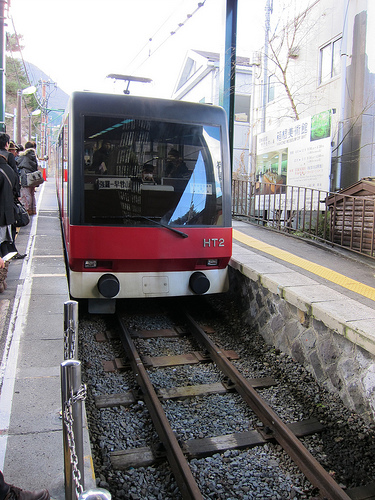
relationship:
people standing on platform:
[0, 132, 21, 244] [1, 178, 62, 496]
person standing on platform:
[8, 139, 16, 156] [1, 178, 62, 496]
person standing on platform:
[25, 138, 35, 151] [1, 178, 62, 496]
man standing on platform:
[0, 149, 16, 262] [1, 178, 62, 496]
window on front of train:
[75, 110, 232, 229] [49, 87, 236, 316]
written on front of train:
[195, 234, 229, 251] [51, 95, 256, 301]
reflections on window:
[95, 138, 215, 214] [82, 116, 226, 226]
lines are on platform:
[23, 195, 43, 426] [1, 176, 71, 496]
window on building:
[317, 32, 345, 86] [250, 0, 368, 225]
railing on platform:
[241, 172, 369, 250] [220, 205, 372, 450]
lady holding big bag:
[9, 138, 54, 231] [20, 170, 47, 190]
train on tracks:
[49, 87, 236, 316] [94, 311, 373, 499]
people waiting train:
[0, 128, 47, 273] [49, 87, 236, 316]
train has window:
[49, 87, 236, 316] [82, 116, 226, 226]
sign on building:
[233, 111, 373, 243] [232, 60, 373, 219]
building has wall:
[250, 0, 375, 261] [253, 0, 368, 219]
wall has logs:
[253, 0, 368, 219] [321, 173, 374, 261]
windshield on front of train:
[71, 114, 210, 231] [49, 87, 236, 316]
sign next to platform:
[252, 107, 337, 213] [220, 205, 372, 450]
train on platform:
[49, 87, 236, 316] [6, 179, 372, 498]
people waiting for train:
[0, 128, 47, 273] [49, 87, 236, 316]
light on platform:
[4, 69, 43, 150] [0, 137, 58, 343]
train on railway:
[49, 87, 236, 316] [79, 294, 375, 499]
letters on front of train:
[202, 236, 215, 246] [52, 72, 232, 298]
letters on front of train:
[275, 121, 308, 145] [52, 72, 232, 298]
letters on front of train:
[258, 135, 276, 147] [52, 72, 232, 298]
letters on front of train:
[289, 146, 324, 193] [52, 72, 232, 298]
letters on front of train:
[255, 194, 324, 209] [52, 72, 232, 298]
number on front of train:
[218, 235, 223, 247] [52, 72, 232, 298]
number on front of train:
[121, 178, 125, 189] [52, 72, 232, 298]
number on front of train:
[105, 179, 110, 189] [52, 72, 232, 298]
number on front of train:
[113, 179, 119, 188] [52, 72, 232, 298]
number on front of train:
[100, 181, 105, 189] [52, 72, 232, 298]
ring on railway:
[58, 356, 81, 369] [100, 305, 306, 410]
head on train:
[73, 91, 230, 116] [49, 87, 236, 316]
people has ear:
[0, 132, 21, 244] [5, 137, 11, 148]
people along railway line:
[0, 132, 21, 244] [60, 311, 251, 373]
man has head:
[0, 130, 28, 256] [1, 130, 13, 150]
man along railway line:
[0, 130, 28, 256] [0, 129, 46, 315]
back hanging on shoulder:
[18, 166, 43, 190] [27, 151, 36, 163]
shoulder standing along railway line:
[27, 151, 36, 163] [1, 185, 46, 473]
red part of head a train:
[70, 227, 229, 268] [47, 85, 226, 299]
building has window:
[250, 0, 368, 225] [317, 37, 344, 83]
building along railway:
[250, 0, 368, 225] [79, 294, 375, 499]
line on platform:
[229, 219, 375, 302] [220, 178, 373, 321]